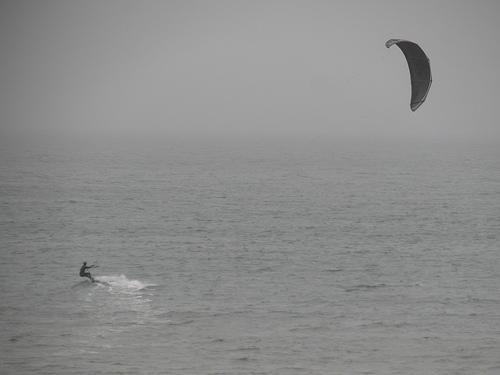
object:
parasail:
[384, 38, 434, 111]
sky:
[1, 1, 498, 150]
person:
[78, 261, 95, 282]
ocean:
[1, 144, 500, 374]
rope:
[92, 44, 417, 269]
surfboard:
[89, 274, 101, 284]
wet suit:
[79, 265, 91, 277]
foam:
[95, 274, 147, 292]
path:
[111, 285, 151, 327]